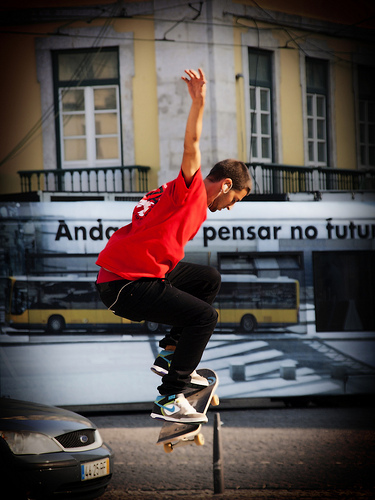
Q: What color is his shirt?
A: Red.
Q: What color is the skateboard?
A: Black.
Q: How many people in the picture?
A: One.